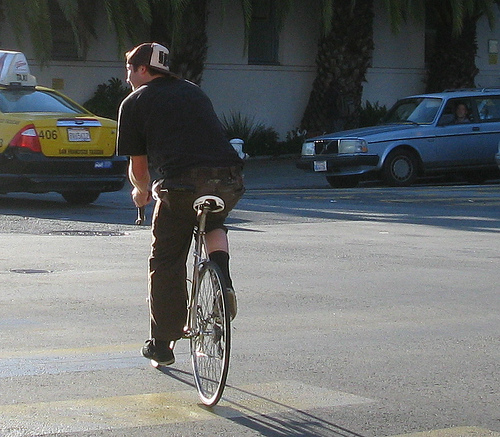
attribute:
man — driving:
[452, 102, 471, 124]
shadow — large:
[157, 363, 365, 437]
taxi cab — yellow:
[0, 45, 130, 207]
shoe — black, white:
[140, 339, 177, 368]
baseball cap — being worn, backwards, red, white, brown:
[123, 41, 185, 79]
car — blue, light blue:
[295, 85, 500, 188]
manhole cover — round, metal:
[47, 227, 126, 239]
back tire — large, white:
[189, 256, 234, 409]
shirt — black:
[111, 75, 242, 169]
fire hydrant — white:
[228, 136, 250, 181]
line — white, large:
[0, 374, 377, 437]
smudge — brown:
[120, 393, 209, 424]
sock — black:
[208, 248, 234, 287]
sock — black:
[153, 337, 169, 350]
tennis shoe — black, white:
[215, 283, 239, 322]